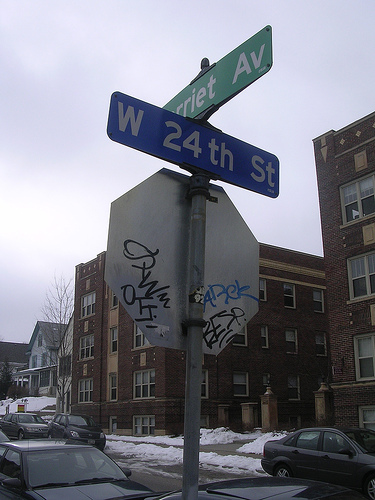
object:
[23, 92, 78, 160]
sky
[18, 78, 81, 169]
sky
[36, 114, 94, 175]
sky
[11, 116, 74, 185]
sky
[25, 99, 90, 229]
sky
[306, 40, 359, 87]
sky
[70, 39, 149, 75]
sky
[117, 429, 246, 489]
ground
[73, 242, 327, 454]
building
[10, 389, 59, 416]
yard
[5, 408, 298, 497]
street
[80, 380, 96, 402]
windows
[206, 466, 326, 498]
sunroof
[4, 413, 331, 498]
street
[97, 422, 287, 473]
snow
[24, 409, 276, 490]
street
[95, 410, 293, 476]
snow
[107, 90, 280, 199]
blue sign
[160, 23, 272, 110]
green sign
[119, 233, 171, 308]
grafitti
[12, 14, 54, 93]
white clouds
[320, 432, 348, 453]
window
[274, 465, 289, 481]
tire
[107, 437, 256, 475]
snow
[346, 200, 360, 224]
window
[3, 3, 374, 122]
sky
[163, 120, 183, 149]
number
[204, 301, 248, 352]
writing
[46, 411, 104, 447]
cars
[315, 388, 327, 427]
stone columns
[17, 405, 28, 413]
sign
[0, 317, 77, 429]
houses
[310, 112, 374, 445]
building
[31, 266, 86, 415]
tree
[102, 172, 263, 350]
back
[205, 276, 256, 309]
graffiti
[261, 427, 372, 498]
car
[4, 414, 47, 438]
suv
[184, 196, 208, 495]
pole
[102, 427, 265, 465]
sidewalk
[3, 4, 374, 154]
sky